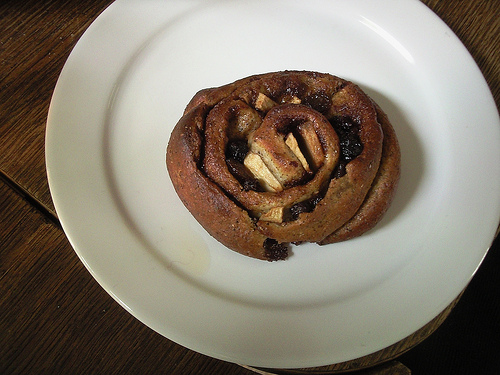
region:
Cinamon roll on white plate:
[129, 69, 412, 266]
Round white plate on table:
[45, 4, 499, 369]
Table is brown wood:
[2, 1, 497, 372]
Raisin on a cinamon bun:
[222, 132, 268, 177]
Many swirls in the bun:
[166, 58, 408, 262]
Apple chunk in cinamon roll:
[230, 111, 290, 202]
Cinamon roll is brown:
[151, 61, 497, 266]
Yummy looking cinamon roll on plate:
[168, 65, 422, 275]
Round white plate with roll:
[43, 8, 497, 356]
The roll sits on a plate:
[133, 68, 417, 270]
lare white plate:
[65, 3, 440, 351]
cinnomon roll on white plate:
[167, 38, 417, 273]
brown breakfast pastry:
[191, 53, 413, 260]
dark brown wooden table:
[13, 166, 68, 343]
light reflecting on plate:
[331, 13, 430, 75]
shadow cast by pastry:
[362, 83, 447, 245]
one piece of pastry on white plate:
[112, 14, 440, 309]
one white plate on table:
[39, 0, 486, 352]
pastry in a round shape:
[163, 57, 401, 252]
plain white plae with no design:
[43, 23, 461, 329]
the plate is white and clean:
[22, 57, 444, 349]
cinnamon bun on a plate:
[160, 71, 404, 260]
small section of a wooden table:
[0, 232, 68, 374]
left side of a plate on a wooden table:
[0, 0, 167, 373]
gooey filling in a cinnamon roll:
[332, 114, 365, 161]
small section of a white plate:
[125, 2, 419, 71]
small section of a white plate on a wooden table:
[400, 0, 499, 330]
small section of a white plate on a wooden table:
[115, 269, 441, 374]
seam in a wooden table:
[0, 167, 62, 229]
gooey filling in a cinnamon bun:
[222, 132, 249, 162]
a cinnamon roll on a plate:
[165, 68, 407, 263]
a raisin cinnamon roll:
[114, 13, 466, 289]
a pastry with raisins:
[76, 7, 498, 292]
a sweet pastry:
[132, 20, 422, 355]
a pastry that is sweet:
[141, 21, 456, 293]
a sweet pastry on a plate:
[47, 10, 450, 349]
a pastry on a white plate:
[129, 22, 498, 292]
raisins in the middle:
[166, 49, 416, 284]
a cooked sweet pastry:
[126, 60, 461, 299]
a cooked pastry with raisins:
[160, 27, 399, 248]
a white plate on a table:
[27, 2, 414, 370]